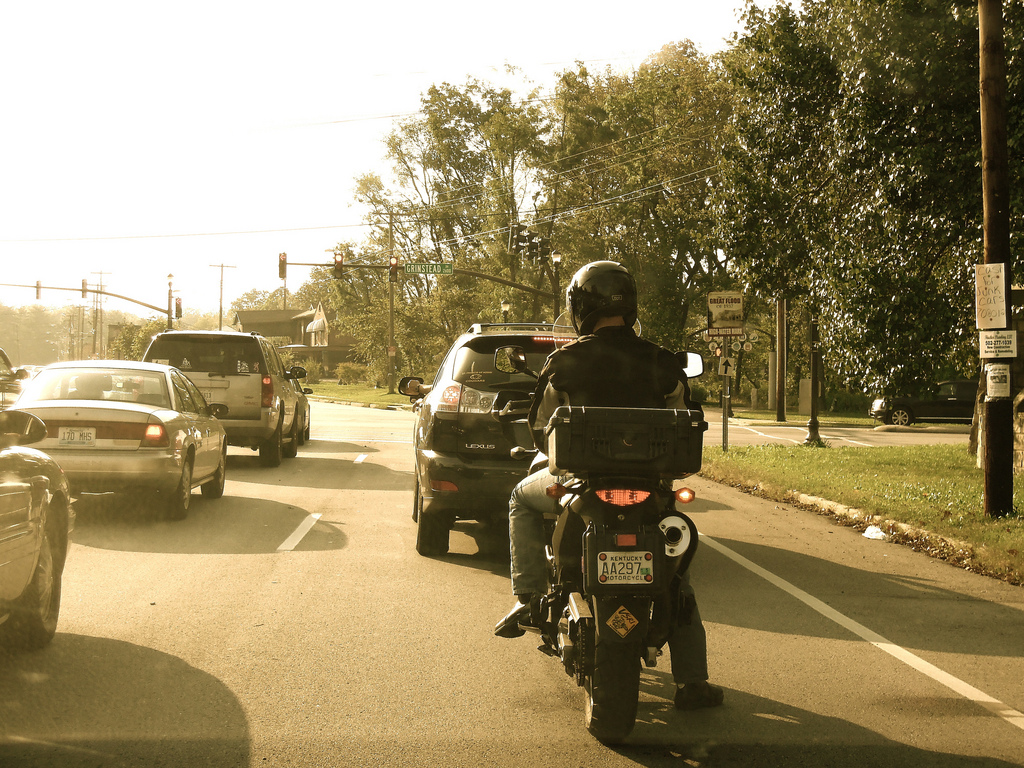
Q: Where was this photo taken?
A: On street.